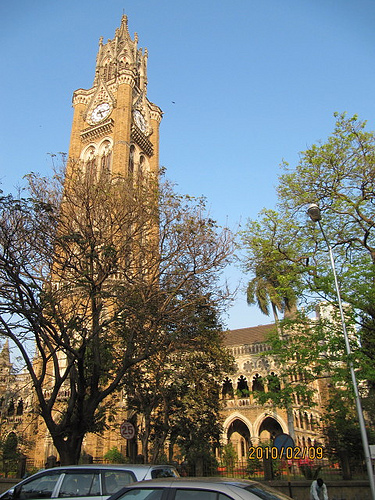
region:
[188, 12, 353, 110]
a blue sky in the background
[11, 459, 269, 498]
part of two cars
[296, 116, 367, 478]
a large tree to the right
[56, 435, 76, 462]
the tree thick stem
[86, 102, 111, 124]
a clock in the tower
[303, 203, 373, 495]
a tall street lamp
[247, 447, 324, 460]
the date is 2010/02/09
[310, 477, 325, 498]
a man in a white shirt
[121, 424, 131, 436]
the number 25 in red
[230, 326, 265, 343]
the roof of the building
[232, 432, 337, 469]
Numbers in the shot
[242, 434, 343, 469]
The numbers are yellow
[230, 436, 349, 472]
This is a the date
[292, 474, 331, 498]
A person below the date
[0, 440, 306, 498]
Cars are driving by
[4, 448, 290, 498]
These cars are silver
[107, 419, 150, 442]
"25" is on the sign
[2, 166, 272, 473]
Trees are in the shot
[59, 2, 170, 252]
This is a clock tower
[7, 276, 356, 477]
A building in the background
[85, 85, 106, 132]
clock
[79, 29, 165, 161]
clock tower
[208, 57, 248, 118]
white clouds in blue sky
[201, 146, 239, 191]
white clouds in blue sky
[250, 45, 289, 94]
white clouds in blue sky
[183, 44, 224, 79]
white clouds in blue sky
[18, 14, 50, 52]
white clouds in blue sky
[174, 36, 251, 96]
white clouds in blue sky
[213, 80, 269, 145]
white clouds in blue sky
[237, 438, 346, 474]
date stamp on picture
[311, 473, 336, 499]
man bending down in front of building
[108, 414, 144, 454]
the number 25 on sign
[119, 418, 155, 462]
a red and white sign beside car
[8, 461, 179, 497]
silver hatchback beside sign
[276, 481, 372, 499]
brick wall in front of building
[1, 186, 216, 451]
large tree beside building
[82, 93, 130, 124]
clock on top of building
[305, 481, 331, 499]
man wearing silver shirt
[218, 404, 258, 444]
large arches on building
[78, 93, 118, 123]
clock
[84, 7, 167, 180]
brown clock tower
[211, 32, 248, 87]
white clouds in blue sky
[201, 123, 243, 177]
white clouds in blue sky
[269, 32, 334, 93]
white clouds in blue sky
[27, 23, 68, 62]
white clouds in blue sky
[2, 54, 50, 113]
white clouds in blue sky